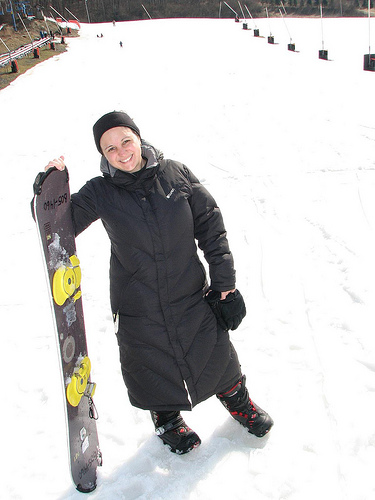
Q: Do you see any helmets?
A: No, there are no helmets.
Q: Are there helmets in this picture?
A: No, there are no helmets.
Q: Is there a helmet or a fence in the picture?
A: No, there are no helmets or fences.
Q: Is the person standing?
A: Yes, the person is standing.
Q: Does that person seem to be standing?
A: Yes, the person is standing.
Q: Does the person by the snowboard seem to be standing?
A: Yes, the person is standing.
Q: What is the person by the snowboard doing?
A: The person is standing.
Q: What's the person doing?
A: The person is standing.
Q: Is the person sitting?
A: No, the person is standing.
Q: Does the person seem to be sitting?
A: No, the person is standing.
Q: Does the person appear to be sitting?
A: No, the person is standing.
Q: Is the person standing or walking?
A: The person is standing.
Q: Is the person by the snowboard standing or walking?
A: The person is standing.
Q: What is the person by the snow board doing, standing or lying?
A: The person is standing.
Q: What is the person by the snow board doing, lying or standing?
A: The person is standing.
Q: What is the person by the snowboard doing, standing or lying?
A: The person is standing.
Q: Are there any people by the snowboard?
A: Yes, there is a person by the snowboard.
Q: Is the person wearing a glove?
A: Yes, the person is wearing a glove.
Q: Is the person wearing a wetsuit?
A: No, the person is wearing a glove.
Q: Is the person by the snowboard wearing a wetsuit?
A: No, the person is wearing a glove.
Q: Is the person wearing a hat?
A: Yes, the person is wearing a hat.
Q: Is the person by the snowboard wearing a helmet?
A: No, the person is wearing a hat.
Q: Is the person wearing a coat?
A: Yes, the person is wearing a coat.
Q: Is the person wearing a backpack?
A: No, the person is wearing a coat.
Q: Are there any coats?
A: Yes, there is a coat.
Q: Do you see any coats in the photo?
A: Yes, there is a coat.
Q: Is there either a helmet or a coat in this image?
A: Yes, there is a coat.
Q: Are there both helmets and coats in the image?
A: No, there is a coat but no helmets.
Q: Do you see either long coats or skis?
A: Yes, there is a long coat.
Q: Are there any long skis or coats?
A: Yes, there is a long coat.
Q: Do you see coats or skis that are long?
A: Yes, the coat is long.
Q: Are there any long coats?
A: Yes, there is a long coat.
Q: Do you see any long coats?
A: Yes, there is a long coat.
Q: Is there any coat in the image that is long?
A: Yes, there is a coat that is long.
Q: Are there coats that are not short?
A: Yes, there is a long coat.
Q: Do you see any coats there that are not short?
A: Yes, there is a long coat.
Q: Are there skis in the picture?
A: No, there are no skis.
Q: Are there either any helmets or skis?
A: No, there are no skis or helmets.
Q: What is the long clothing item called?
A: The clothing item is a coat.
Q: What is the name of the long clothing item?
A: The clothing item is a coat.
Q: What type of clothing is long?
A: The clothing is a coat.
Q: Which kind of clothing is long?
A: The clothing is a coat.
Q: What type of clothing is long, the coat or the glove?
A: The coat is long.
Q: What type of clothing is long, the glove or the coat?
A: The coat is long.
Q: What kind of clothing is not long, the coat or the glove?
A: The glove is not long.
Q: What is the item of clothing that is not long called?
A: The clothing item is a glove.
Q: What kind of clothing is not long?
A: The clothing is a glove.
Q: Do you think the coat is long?
A: Yes, the coat is long.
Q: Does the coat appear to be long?
A: Yes, the coat is long.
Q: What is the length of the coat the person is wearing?
A: The coat is long.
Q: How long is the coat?
A: The coat is long.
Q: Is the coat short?
A: No, the coat is long.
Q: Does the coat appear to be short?
A: No, the coat is long.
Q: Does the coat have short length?
A: No, the coat is long.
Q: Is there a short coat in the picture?
A: No, there is a coat but it is long.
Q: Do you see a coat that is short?
A: No, there is a coat but it is long.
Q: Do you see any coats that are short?
A: No, there is a coat but it is long.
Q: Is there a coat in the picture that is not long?
A: No, there is a coat but it is long.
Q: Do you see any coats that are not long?
A: No, there is a coat but it is long.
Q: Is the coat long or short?
A: The coat is long.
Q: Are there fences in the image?
A: No, there are no fences.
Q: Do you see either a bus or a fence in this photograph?
A: No, there are no fences or buses.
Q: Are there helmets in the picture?
A: No, there are no helmets.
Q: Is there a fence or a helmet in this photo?
A: No, there are no helmets or fences.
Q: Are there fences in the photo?
A: No, there are no fences.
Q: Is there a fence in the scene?
A: No, there are no fences.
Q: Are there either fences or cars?
A: No, there are no fences or cars.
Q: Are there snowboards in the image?
A: Yes, there is a snowboard.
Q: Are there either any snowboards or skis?
A: Yes, there is a snowboard.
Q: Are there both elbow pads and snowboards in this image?
A: No, there is a snowboard but no elbow pads.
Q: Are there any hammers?
A: No, there are no hammers.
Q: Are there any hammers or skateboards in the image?
A: No, there are no hammers or skateboards.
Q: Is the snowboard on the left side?
A: Yes, the snowboard is on the left of the image.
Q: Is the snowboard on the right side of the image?
A: No, the snowboard is on the left of the image.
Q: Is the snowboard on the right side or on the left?
A: The snowboard is on the left of the image.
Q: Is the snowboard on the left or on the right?
A: The snowboard is on the left of the image.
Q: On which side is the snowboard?
A: The snowboard is on the left of the image.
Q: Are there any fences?
A: No, there are no fences.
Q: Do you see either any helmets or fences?
A: No, there are no fences or helmets.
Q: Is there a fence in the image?
A: No, there are no fences.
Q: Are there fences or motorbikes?
A: No, there are no fences or motorbikes.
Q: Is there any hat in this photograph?
A: Yes, there is a hat.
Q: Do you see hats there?
A: Yes, there is a hat.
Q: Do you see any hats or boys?
A: Yes, there is a hat.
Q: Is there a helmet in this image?
A: No, there are no helmets.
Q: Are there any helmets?
A: No, there are no helmets.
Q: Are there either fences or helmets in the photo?
A: No, there are no helmets or fences.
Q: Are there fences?
A: No, there are no fences.